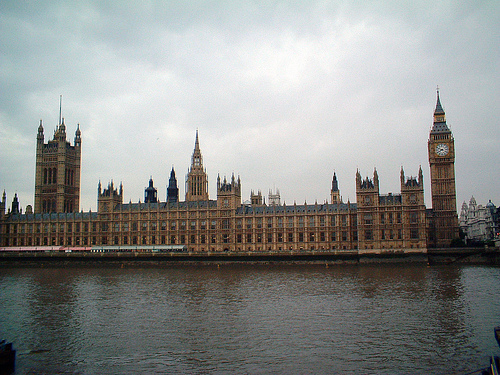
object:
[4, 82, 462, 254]
parliment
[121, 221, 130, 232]
windows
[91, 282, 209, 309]
waves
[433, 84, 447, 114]
pinnacle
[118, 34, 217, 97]
clouds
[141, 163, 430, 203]
background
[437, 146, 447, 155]
face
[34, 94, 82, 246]
tower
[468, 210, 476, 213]
canopies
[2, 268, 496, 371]
river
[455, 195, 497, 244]
buildings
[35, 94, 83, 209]
towers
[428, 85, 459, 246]
clock tower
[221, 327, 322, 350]
ripples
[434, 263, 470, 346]
reflection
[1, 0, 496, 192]
sky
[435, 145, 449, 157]
clock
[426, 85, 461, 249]
tower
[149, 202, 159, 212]
shingles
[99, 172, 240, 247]
side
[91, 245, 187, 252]
train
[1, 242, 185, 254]
canopies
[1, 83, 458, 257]
building